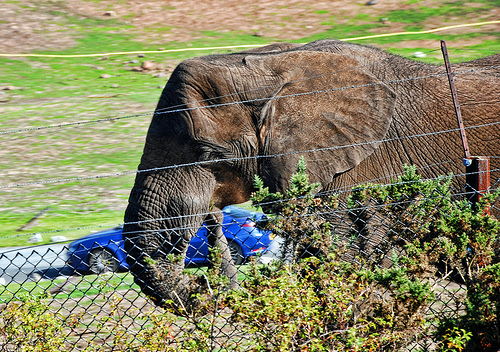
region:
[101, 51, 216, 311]
elephant has wrinkled trunk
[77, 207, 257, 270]
blue car behind elephant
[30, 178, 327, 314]
sports car on road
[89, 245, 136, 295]
car has black tires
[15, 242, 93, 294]
road is light grey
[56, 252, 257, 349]
chain link fence in front of elephant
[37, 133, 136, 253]
green field behind road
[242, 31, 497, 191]
elephant has short hair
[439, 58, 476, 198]
red pole next to elephant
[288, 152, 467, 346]
green bush in front of elephant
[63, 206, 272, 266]
Blue car behind the elephant.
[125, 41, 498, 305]
Grey older elephant.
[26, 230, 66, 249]
Rocks by the road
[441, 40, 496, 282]
Metal holding the fence up.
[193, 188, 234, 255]
Elephant is eating with his trunk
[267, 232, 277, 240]
Yellow plate on the blue car.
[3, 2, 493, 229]
Field behind the elephant.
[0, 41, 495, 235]
Fence holding the elephant.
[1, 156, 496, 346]
Green plants in front of the elephant.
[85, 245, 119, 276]
Black and silver tire on the blue car.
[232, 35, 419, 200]
the left ear of an elephant.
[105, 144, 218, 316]
a trunk on an elephant.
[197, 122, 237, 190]
the left eye of an elephant.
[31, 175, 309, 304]
a blue car on a road.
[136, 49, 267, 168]
the forehead of an elephant.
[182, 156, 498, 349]
a green bush near an elephant.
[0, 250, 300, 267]
a paved road with a car.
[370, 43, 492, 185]
the body of an elephant.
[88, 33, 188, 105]
a bunch of rocks on a hill.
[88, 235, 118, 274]
the left front tire of a blue car.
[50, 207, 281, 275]
Sporty blue car in background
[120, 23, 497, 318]
Adult brown elephant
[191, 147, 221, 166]
Eye of an adult elephant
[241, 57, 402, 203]
Ear of an adult elephant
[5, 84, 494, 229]
Barbed wire fence containing elephant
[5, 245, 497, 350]
Chain link fence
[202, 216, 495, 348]
Shrubs growing on chain link fence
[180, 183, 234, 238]
Elephant eating plant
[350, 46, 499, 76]
Elephant back hair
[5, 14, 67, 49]
Brown patch of grass in background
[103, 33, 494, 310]
the elephant is big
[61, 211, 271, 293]
a blue car on the road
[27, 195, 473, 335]
a fence to the right of the elephant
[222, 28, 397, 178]
the ear is flat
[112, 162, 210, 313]
the trunk is wide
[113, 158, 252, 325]
the trunks is at the mouth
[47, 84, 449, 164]
the fence is made of wire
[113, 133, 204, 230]
the skin is wrinkled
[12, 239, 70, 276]
the road is grey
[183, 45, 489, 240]
the elephant is brown